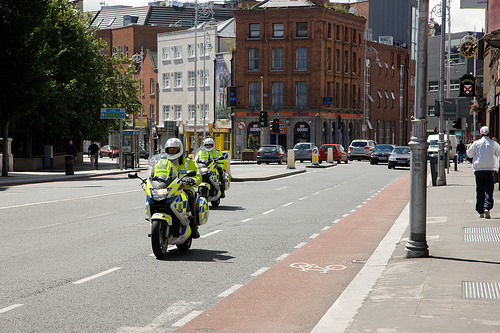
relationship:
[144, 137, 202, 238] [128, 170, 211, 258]
person on motorcycle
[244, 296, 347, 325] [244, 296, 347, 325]
lane along lane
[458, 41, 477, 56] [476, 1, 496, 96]
clock along side of building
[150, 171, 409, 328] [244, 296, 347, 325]
bicycle lane next to lane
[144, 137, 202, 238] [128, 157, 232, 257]
person with motorcycles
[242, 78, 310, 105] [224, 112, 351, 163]
apartment above store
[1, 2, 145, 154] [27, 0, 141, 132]
tree with leaves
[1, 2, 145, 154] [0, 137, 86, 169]
tree behind wall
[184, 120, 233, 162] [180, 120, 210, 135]
storefront with sign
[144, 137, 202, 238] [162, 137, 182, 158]
person with helmet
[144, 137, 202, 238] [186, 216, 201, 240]
person with boots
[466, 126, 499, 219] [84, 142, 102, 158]
person with shirt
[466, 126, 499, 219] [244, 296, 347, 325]
person walking up lane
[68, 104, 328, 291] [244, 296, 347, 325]
motorcycles on lane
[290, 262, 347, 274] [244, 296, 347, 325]
indicator on lane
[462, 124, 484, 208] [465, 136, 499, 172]
person wearing white jacket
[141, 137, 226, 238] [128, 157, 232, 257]
people riding motorcycles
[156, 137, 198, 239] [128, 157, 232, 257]
people riding motorcycles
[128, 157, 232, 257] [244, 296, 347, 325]
motorcycles on lane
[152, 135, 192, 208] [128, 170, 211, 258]
person riding motorcycle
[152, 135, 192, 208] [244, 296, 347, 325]
person riding down lane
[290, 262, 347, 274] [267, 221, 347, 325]
indicator on lane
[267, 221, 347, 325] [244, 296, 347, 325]
lane on lane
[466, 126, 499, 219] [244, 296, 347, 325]
person walking down lane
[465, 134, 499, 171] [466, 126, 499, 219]
white jacket on person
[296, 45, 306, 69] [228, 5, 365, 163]
window on side of building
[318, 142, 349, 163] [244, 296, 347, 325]
car on lane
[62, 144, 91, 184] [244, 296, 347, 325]
trash can on lane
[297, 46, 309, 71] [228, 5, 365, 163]
window in building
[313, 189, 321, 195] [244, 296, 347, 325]
line on lane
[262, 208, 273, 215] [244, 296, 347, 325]
line on lane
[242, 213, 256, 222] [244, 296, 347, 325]
line on lane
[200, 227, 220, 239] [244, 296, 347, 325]
line on lane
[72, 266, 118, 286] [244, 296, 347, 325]
line on lane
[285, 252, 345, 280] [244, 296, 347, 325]
indicator on lane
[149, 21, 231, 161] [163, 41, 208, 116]
building has facade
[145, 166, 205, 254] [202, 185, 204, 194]
motorcycle has wheel